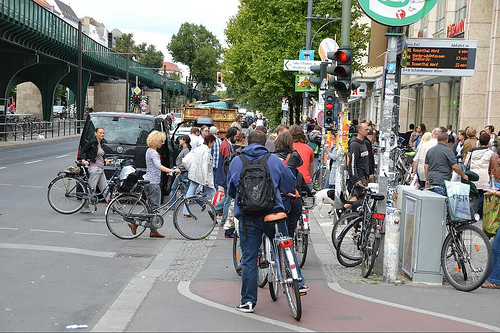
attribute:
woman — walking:
[147, 130, 181, 238]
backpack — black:
[236, 153, 274, 217]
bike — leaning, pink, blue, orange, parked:
[338, 192, 381, 278]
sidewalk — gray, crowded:
[192, 162, 498, 332]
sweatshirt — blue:
[226, 143, 295, 214]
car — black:
[80, 111, 175, 197]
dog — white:
[116, 165, 134, 181]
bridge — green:
[2, 1, 201, 122]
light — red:
[333, 47, 349, 64]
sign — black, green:
[399, 48, 475, 70]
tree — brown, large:
[225, 1, 373, 128]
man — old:
[426, 133, 468, 196]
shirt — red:
[287, 143, 315, 185]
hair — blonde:
[147, 130, 167, 149]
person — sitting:
[230, 152, 298, 219]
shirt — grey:
[425, 146, 459, 186]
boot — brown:
[150, 231, 164, 238]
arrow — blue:
[284, 57, 290, 71]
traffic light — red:
[334, 49, 350, 101]